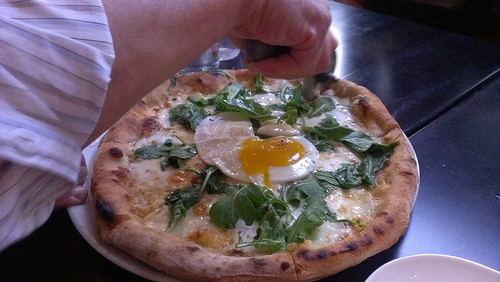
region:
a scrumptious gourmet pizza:
[9, 6, 491, 273]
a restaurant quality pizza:
[94, 75, 417, 272]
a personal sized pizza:
[102, 78, 409, 268]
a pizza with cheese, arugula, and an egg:
[102, 60, 404, 275]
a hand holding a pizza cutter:
[237, 0, 339, 85]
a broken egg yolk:
[238, 131, 310, 177]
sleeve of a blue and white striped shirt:
[1, 4, 78, 231]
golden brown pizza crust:
[357, 81, 425, 233]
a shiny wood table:
[342, 10, 499, 82]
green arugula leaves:
[206, 175, 328, 244]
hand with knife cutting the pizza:
[240, 2, 337, 76]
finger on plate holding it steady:
[67, 186, 87, 203]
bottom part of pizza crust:
[132, 235, 192, 260]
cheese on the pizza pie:
[331, 191, 368, 218]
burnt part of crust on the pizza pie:
[93, 195, 117, 222]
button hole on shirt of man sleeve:
[9, 128, 41, 151]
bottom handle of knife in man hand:
[244, 40, 269, 61]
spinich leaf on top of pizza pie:
[219, 98, 269, 115]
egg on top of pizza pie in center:
[201, 121, 313, 181]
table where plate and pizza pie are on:
[366, 31, 493, 84]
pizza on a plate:
[95, 50, 422, 271]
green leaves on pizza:
[125, 71, 390, 243]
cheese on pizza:
[132, 96, 375, 246]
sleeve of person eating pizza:
[2, 7, 104, 227]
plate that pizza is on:
[67, 131, 189, 276]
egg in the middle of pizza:
[195, 96, 325, 191]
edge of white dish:
[360, 247, 494, 280]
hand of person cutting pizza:
[226, 2, 358, 94]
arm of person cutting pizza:
[100, 0, 260, 127]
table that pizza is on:
[26, 7, 496, 271]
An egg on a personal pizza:
[199, 105, 316, 203]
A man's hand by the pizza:
[2, 2, 375, 95]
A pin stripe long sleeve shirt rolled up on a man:
[1, 2, 113, 249]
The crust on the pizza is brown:
[94, 173, 429, 260]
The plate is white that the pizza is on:
[60, 55, 425, 280]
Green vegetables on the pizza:
[160, 175, 380, 237]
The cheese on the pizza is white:
[128, 142, 271, 253]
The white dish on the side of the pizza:
[328, 232, 490, 279]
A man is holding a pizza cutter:
[227, 30, 363, 104]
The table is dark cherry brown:
[337, 15, 497, 250]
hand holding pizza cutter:
[210, 0, 363, 94]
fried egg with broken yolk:
[191, 98, 328, 195]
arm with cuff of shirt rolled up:
[4, 2, 337, 156]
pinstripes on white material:
[2, 1, 106, 148]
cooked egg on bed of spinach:
[147, 85, 408, 268]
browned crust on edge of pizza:
[371, 70, 428, 252]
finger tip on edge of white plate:
[45, 167, 101, 219]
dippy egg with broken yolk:
[191, 99, 326, 190]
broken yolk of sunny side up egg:
[194, 105, 330, 194]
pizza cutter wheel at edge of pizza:
[282, 25, 366, 110]